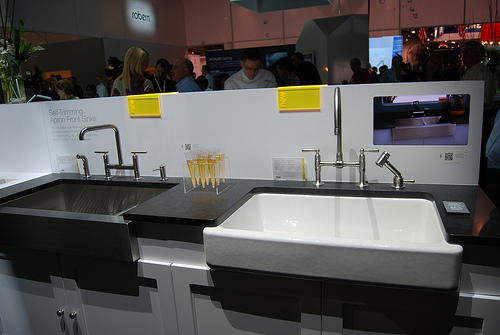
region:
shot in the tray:
[181, 150, 198, 187]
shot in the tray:
[193, 156, 208, 191]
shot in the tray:
[206, 155, 216, 185]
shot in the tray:
[213, 155, 223, 185]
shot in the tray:
[220, 150, 230, 180]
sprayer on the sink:
[372, 150, 414, 188]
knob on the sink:
[301, 145, 329, 187]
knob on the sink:
[360, 139, 387, 191]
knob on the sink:
[128, 147, 152, 178]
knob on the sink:
[93, 143, 113, 173]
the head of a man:
[158, 58, 200, 85]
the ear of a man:
[234, 55, 276, 79]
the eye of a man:
[241, 51, 272, 83]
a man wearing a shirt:
[223, 51, 284, 88]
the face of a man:
[238, 51, 276, 81]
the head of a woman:
[114, 40, 169, 87]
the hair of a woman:
[116, 34, 176, 79]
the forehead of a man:
[241, 51, 274, 81]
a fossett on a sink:
[55, 105, 147, 185]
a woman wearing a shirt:
[111, 39, 181, 92]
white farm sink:
[203, 188, 476, 288]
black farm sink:
[0, 163, 177, 258]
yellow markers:
[272, 83, 328, 110]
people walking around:
[31, 37, 497, 85]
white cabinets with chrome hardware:
[1, 250, 496, 330]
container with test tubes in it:
[178, 145, 228, 195]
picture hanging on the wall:
[365, 92, 476, 144]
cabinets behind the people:
[181, 0, 488, 43]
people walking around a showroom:
[15, 31, 485, 102]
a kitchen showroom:
[2, 103, 487, 331]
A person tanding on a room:
[227, 49, 266, 80]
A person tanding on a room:
[168, 54, 200, 94]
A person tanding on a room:
[113, 43, 152, 96]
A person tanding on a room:
[460, 34, 481, 99]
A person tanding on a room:
[340, 46, 368, 76]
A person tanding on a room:
[186, 38, 215, 73]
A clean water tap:
[245, 170, 441, 259]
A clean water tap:
[36, 157, 100, 208]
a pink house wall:
[180, 5, 240, 35]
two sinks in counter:
[10, 98, 489, 315]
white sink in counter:
[209, 165, 473, 303]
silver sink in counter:
[6, 160, 158, 275]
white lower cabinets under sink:
[6, 220, 427, 333]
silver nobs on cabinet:
[44, 291, 98, 331]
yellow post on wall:
[119, 84, 349, 147]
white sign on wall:
[30, 97, 140, 165]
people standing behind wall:
[57, 20, 492, 113]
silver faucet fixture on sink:
[282, 76, 409, 208]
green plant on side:
[1, 4, 59, 137]